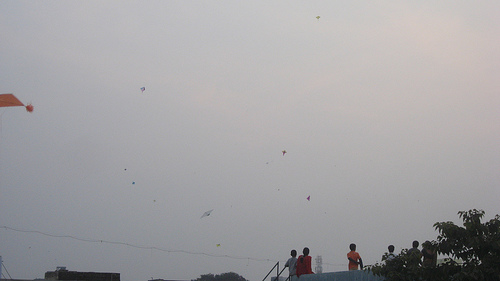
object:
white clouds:
[368, 77, 377, 81]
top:
[40, 264, 123, 280]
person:
[284, 248, 299, 276]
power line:
[6, 225, 276, 262]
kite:
[140, 86, 145, 92]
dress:
[296, 254, 316, 276]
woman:
[296, 246, 317, 278]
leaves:
[434, 224, 442, 231]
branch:
[432, 220, 465, 236]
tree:
[361, 205, 500, 280]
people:
[383, 244, 401, 264]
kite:
[199, 208, 216, 220]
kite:
[0, 93, 35, 114]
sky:
[0, 0, 500, 279]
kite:
[306, 195, 311, 201]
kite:
[282, 149, 288, 156]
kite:
[316, 15, 321, 19]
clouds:
[278, 40, 288, 45]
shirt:
[346, 250, 362, 270]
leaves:
[467, 233, 470, 237]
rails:
[262, 262, 279, 281]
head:
[349, 243, 357, 252]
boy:
[346, 242, 363, 270]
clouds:
[413, 52, 417, 56]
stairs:
[271, 265, 291, 280]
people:
[419, 239, 438, 268]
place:
[260, 259, 389, 280]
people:
[404, 239, 424, 269]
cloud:
[0, 0, 500, 281]